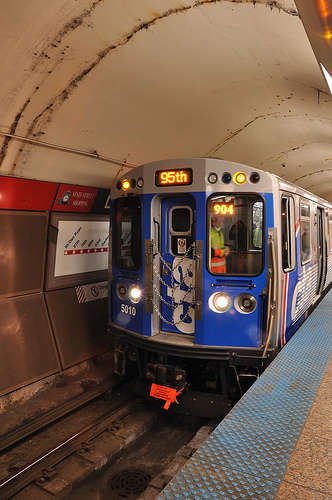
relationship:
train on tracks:
[107, 156, 332, 415] [45, 375, 159, 434]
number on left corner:
[116, 301, 136, 319] [104, 299, 151, 337]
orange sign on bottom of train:
[149, 382, 181, 409] [112, 156, 330, 414]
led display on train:
[156, 163, 195, 189] [107, 156, 332, 415]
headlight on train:
[207, 291, 230, 317] [112, 156, 330, 414]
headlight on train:
[124, 283, 144, 308] [112, 156, 330, 414]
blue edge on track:
[154, 290, 330, 498] [2, 365, 239, 478]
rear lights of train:
[123, 169, 246, 193] [97, 168, 326, 408]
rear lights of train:
[118, 287, 256, 315] [97, 168, 326, 408]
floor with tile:
[134, 283, 330, 498] [193, 415, 300, 482]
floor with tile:
[134, 283, 330, 498] [156, 459, 281, 499]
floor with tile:
[134, 283, 330, 498] [281, 432, 330, 492]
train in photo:
[112, 156, 330, 414] [1, 0, 328, 498]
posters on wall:
[54, 220, 107, 279] [0, 175, 110, 398]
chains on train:
[149, 242, 195, 326] [99, 153, 331, 388]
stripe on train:
[281, 271, 290, 344] [99, 153, 331, 388]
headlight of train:
[208, 291, 230, 314] [76, 153, 321, 363]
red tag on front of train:
[149, 381, 182, 409] [110, 157, 330, 365]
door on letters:
[150, 189, 199, 341] [167, 256, 194, 331]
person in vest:
[201, 212, 230, 275] [211, 229, 227, 251]